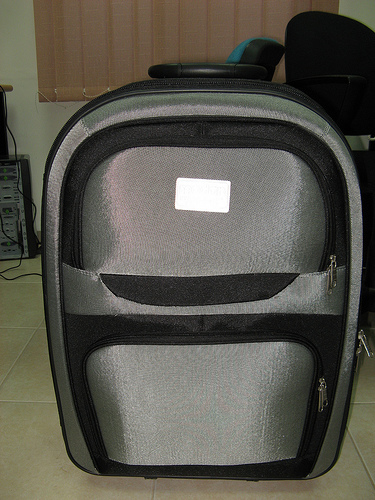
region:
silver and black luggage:
[38, 74, 366, 484]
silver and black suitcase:
[36, 71, 363, 487]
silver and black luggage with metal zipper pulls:
[39, 82, 363, 482]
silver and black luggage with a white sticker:
[39, 91, 361, 477]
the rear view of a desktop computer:
[0, 155, 32, 263]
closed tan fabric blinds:
[30, 4, 108, 105]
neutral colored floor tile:
[0, 358, 49, 439]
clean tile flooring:
[0, 373, 46, 470]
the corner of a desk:
[0, 77, 12, 101]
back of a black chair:
[281, 9, 373, 103]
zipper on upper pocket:
[319, 248, 343, 305]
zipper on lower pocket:
[312, 374, 330, 417]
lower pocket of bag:
[74, 332, 325, 475]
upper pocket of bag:
[66, 136, 354, 287]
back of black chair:
[280, 7, 373, 136]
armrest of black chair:
[286, 66, 367, 94]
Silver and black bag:
[35, 73, 368, 486]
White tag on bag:
[166, 169, 236, 223]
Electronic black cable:
[0, 89, 40, 284]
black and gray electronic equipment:
[1, 156, 36, 266]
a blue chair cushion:
[226, 36, 280, 64]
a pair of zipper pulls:
[316, 376, 330, 414]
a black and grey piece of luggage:
[37, 58, 371, 496]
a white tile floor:
[2, 225, 363, 497]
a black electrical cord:
[0, 226, 40, 288]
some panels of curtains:
[28, 0, 344, 104]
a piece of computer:
[0, 151, 39, 258]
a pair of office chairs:
[145, 9, 373, 204]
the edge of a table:
[0, 81, 16, 95]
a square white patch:
[172, 173, 230, 214]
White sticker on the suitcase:
[169, 170, 237, 219]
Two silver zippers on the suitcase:
[313, 376, 331, 414]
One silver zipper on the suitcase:
[354, 328, 374, 359]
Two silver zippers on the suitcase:
[319, 252, 345, 299]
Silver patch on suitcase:
[84, 341, 321, 464]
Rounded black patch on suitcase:
[94, 266, 306, 305]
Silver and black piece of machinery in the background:
[0, 150, 36, 264]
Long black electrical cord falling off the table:
[0, 83, 42, 281]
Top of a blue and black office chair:
[226, 25, 286, 83]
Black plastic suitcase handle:
[147, 60, 267, 77]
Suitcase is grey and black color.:
[17, 98, 374, 478]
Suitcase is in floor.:
[25, 346, 374, 494]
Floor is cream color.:
[6, 370, 96, 499]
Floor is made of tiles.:
[13, 394, 96, 497]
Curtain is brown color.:
[44, 13, 212, 75]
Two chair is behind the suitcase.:
[179, 15, 355, 103]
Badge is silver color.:
[150, 165, 240, 220]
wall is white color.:
[3, 41, 57, 148]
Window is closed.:
[20, 3, 367, 97]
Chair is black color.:
[291, 29, 374, 133]